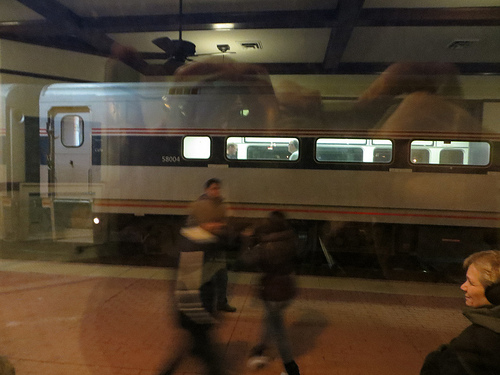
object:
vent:
[233, 37, 263, 51]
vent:
[443, 35, 479, 54]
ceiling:
[1, 0, 499, 75]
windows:
[220, 115, 499, 187]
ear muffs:
[480, 276, 497, 305]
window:
[6, 5, 493, 186]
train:
[30, 62, 497, 268]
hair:
[462, 246, 497, 285]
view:
[438, 240, 494, 337]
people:
[233, 199, 308, 373]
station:
[4, 4, 497, 364]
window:
[409, 137, 491, 169]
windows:
[176, 131, 410, 178]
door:
[39, 104, 105, 252]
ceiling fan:
[130, 34, 235, 65]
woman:
[418, 248, 497, 373]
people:
[173, 176, 242, 326]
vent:
[445, 27, 488, 71]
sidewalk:
[0, 245, 495, 372]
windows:
[166, 130, 484, 170]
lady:
[429, 245, 494, 368]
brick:
[94, 265, 202, 316]